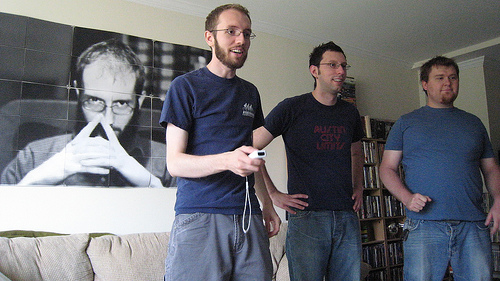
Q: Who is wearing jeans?
A: Two men on right.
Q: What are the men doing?
A: Playing wii.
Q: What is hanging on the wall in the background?
A: Portrait.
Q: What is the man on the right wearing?
A: Tshirt and jeans.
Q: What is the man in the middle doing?
A: Standing with hands on hips.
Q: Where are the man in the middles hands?
A: On hips.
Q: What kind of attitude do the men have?
A: Cheerful.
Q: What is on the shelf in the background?
A: Books.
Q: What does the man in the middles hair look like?
A: Dark Brown.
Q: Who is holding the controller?
A: The man on the left.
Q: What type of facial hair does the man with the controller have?
A: A beard.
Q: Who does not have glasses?
A: The man on the right.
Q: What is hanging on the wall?
A: A picture of a man.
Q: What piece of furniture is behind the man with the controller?
A: A couch.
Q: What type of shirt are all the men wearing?
A: A t-shirt.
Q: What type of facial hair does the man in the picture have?
A: A beard.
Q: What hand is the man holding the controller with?
A: His right.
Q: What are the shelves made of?
A: Wood.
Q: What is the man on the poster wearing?
A: Glasses.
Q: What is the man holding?
A: Remote.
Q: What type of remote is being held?
A: Wii.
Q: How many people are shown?
A: Three.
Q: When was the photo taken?
A: Daytime.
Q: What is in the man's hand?
A: A controller.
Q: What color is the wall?
A: White.